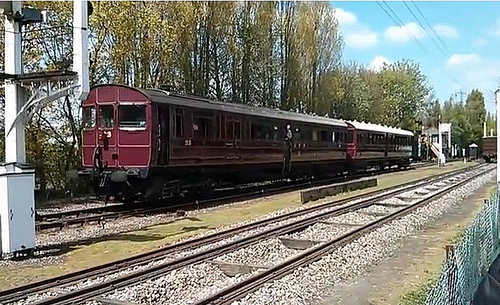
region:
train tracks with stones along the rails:
[5, 158, 498, 298]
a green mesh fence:
[422, 176, 497, 303]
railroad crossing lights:
[1, 0, 94, 260]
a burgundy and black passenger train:
[86, 84, 418, 193]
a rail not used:
[301, 168, 379, 206]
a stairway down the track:
[422, 134, 449, 160]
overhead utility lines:
[378, 0, 499, 105]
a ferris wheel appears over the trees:
[437, 78, 486, 112]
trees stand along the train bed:
[0, 0, 425, 194]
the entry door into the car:
[151, 107, 179, 174]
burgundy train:
[78, 90, 410, 190]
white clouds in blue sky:
[334, 8, 349, 45]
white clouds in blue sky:
[363, 20, 389, 46]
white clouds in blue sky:
[396, 23, 437, 62]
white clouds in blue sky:
[421, 17, 455, 47]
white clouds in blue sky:
[456, 1, 494, 47]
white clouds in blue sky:
[431, 42, 471, 67]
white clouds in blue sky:
[401, 18, 460, 58]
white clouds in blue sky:
[363, 29, 421, 61]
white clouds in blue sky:
[349, 18, 371, 48]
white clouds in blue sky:
[369, 29, 394, 50]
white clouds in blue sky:
[439, 46, 483, 84]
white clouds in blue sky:
[390, 12, 438, 49]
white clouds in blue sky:
[420, 0, 462, 57]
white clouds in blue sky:
[406, 11, 443, 41]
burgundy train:
[108, 95, 335, 166]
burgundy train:
[336, 113, 421, 168]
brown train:
[74, 101, 394, 179]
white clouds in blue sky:
[371, 11, 401, 43]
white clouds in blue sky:
[437, 13, 468, 38]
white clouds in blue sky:
[423, 10, 484, 98]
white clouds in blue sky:
[379, 9, 450, 31]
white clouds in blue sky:
[446, 6, 483, 56]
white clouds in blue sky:
[370, 19, 445, 66]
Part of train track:
[158, 264, 229, 293]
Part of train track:
[268, 218, 348, 245]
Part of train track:
[380, 191, 417, 208]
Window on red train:
[112, 102, 150, 130]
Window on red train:
[75, 98, 115, 133]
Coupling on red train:
[70, 167, 145, 194]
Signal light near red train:
[2, 0, 76, 175]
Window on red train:
[192, 117, 219, 144]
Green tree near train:
[460, 89, 487, 136]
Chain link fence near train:
[467, 237, 484, 289]